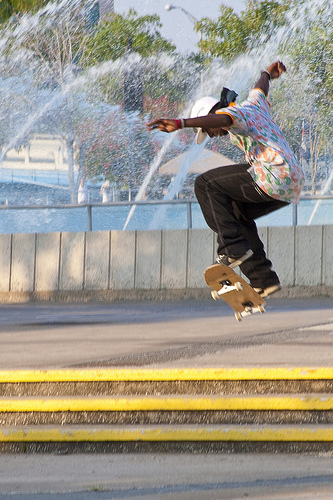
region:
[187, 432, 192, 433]
the line is yellow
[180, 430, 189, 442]
the line is yellow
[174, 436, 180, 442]
the line is yellow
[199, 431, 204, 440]
the line is yellow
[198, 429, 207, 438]
the line is yellow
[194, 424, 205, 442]
the line is yellow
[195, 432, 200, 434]
the line is yellow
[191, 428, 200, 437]
the line is yellow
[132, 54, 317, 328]
The boy is skateboarding.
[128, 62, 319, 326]
The boy and skateboard are airborne.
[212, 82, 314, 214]
The boy's shirt is multicolored.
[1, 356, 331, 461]
The boy is skateboarding over steps.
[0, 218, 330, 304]
A fence is behind the skateboarder.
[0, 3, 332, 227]
Water is spraying up behind the skateboarder.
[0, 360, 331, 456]
The steps are yellow.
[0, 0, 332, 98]
Trees are in the background.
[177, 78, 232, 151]
The boy wears a cap.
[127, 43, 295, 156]
The boy's arms are outstretched.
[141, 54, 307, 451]
a young boy flying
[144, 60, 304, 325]
a person in air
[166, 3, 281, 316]
a big person jumping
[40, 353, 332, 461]
three steps on ground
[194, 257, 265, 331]
a small skating machine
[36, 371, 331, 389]
an yellow line on steps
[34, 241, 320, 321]
a wide wooden wall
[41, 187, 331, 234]
beautiful view of water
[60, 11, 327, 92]
large group of trees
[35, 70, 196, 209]
water jumping in to air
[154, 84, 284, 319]
man is on skateboard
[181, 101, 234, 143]
man wears white hat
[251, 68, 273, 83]
man wears watch on wrist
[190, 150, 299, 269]
man wears black jeans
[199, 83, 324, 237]
man wears multicolor shirt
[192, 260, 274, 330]
skateboard is brown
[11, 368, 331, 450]
yellow paint on steps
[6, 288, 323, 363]
sidewalk is light grey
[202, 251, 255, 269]
man wears black sneakers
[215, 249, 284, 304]
man wears black shoes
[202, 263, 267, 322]
Underneath of a skateboard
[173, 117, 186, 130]
Red and white bracelets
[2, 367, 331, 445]
Three yellow steps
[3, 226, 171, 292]
Short cement wall behind the man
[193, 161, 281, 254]
Black jeans with white accents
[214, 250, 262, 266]
Black shoes with white soles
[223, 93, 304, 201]
Orange and green patterned shirt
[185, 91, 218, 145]
A white baseball cap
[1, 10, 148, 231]
Water spraying up in the air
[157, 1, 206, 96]
Street light on a post